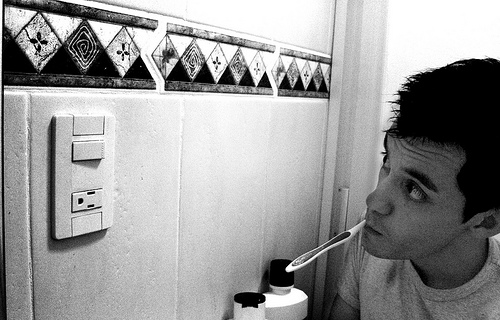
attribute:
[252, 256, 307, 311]
mouthwash — white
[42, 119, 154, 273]
socket — white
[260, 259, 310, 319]
plastic bottle — plastic 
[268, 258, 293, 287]
black lid — black 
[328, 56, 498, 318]
boy — spiky 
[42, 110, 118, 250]
outlet — light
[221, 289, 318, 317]
bottle — squeeze 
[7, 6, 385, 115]
tiles — creative 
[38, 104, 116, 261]
light switch — button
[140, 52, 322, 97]
patterns — diamond 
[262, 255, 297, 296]
bottle — black and white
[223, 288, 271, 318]
bottle — black and white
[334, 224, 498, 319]
shirt — white, short sleeved, light 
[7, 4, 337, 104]
tiles — row 